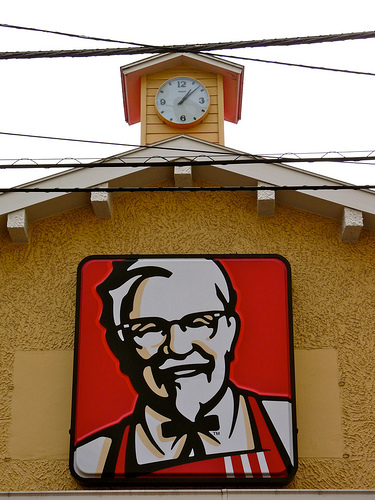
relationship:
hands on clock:
[178, 86, 205, 106] [159, 68, 225, 125]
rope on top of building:
[0, 30, 374, 62] [0, 50, 372, 498]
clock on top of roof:
[155, 75, 211, 129] [2, 124, 373, 206]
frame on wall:
[74, 221, 351, 498] [2, 172, 374, 491]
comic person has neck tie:
[73, 258, 294, 479] [156, 409, 222, 460]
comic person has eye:
[73, 258, 294, 479] [131, 320, 168, 345]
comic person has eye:
[73, 258, 294, 479] [186, 320, 209, 328]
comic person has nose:
[73, 258, 294, 479] [160, 323, 196, 357]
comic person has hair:
[74, 258, 292, 476] [91, 258, 235, 359]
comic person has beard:
[73, 258, 294, 479] [172, 387, 210, 424]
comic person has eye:
[73, 258, 294, 479] [192, 314, 210, 338]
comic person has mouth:
[73, 258, 294, 479] [158, 360, 212, 381]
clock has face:
[155, 75, 211, 129] [157, 77, 207, 120]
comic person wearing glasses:
[73, 258, 294, 479] [109, 307, 228, 349]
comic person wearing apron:
[73, 258, 294, 479] [104, 388, 291, 480]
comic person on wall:
[73, 258, 294, 479] [2, 172, 374, 491]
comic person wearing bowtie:
[73, 258, 294, 479] [146, 413, 233, 459]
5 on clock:
[188, 112, 197, 121] [145, 72, 219, 137]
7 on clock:
[164, 113, 175, 124] [147, 67, 213, 136]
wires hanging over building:
[0, 21, 373, 194] [0, 50, 372, 498]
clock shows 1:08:
[155, 75, 211, 129] [150, 85, 221, 168]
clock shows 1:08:
[155, 75, 211, 129] [153, 72, 217, 151]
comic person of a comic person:
[73, 258, 294, 479] [73, 258, 294, 479]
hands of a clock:
[181, 88, 204, 106] [113, 75, 235, 138]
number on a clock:
[158, 87, 170, 132] [155, 72, 225, 130]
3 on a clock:
[199, 96, 205, 106] [148, 65, 216, 130]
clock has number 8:
[150, 75, 217, 128] [160, 108, 165, 116]